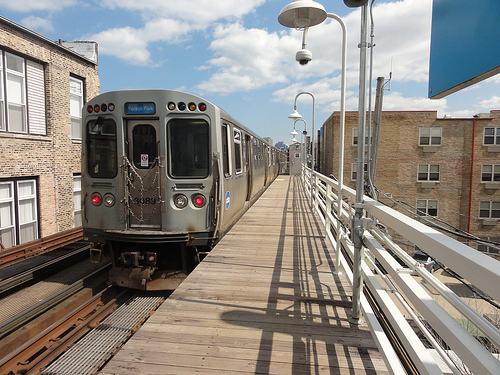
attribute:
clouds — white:
[215, 51, 274, 79]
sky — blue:
[251, 100, 304, 133]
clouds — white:
[125, 50, 207, 65]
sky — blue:
[242, 100, 275, 124]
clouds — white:
[118, 50, 158, 70]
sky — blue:
[244, 100, 283, 130]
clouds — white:
[111, 51, 151, 74]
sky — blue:
[254, 100, 294, 123]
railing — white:
[324, 134, 498, 375]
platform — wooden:
[239, 170, 349, 375]